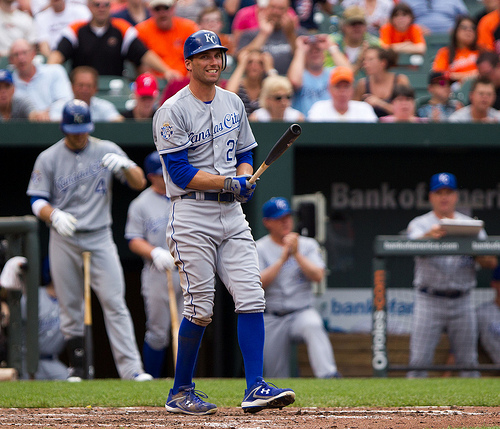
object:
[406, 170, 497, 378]
coach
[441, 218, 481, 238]
clipboard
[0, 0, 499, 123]
crowd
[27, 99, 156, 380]
man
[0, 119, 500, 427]
game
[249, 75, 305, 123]
woman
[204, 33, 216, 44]
white print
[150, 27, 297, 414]
baseball player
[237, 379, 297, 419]
player's feet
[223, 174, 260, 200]
hand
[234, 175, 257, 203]
hand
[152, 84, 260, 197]
jersey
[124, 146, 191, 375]
player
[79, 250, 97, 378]
bat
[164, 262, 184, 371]
bat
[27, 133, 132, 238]
jersey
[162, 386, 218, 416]
blue shoe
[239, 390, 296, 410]
white bottom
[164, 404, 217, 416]
white bottom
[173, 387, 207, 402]
blue shoelace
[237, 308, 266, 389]
blue sock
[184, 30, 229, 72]
baseball cap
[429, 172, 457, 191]
baseball cap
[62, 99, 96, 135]
baseball cap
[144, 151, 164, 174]
baseball cap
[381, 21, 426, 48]
shirt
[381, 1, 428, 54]
man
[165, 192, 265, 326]
gray pants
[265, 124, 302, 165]
bat is black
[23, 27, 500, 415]
people are playing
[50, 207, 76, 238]
glove is white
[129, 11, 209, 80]
shirt is orange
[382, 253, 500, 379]
mesh is dark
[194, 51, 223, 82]
man is smiling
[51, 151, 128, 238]
wearing white gloves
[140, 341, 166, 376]
wearing blue socks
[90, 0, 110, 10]
dark sunglasses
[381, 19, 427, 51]
man wearing orange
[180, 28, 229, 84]
player's head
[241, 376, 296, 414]
blue and white cleat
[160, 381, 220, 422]
player's feet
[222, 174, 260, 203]
blue and gray gloves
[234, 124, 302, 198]
baseball bat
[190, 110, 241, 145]
blue text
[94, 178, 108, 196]
number four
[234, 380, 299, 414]
blue shoe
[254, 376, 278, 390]
blue shoelace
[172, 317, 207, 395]
blue sock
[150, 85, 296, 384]
blue based uniform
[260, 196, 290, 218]
blue baseball cap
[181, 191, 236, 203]
dark colored belt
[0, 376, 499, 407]
green field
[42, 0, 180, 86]
man